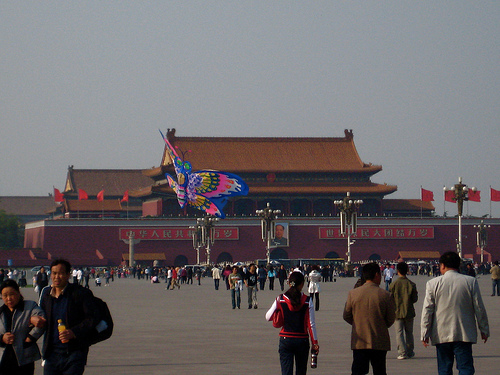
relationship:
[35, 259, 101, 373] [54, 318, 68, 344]
man holding bottle